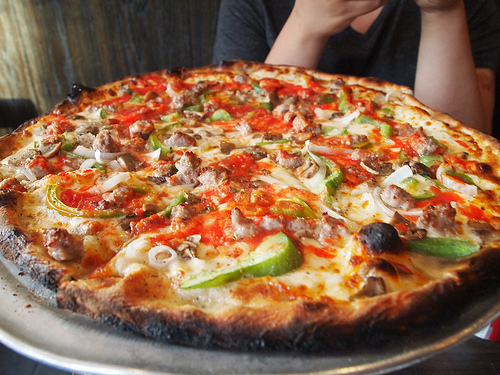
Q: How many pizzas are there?
A: One.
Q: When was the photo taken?
A: Daytime.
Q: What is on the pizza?
A: Toppings.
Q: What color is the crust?
A: Black.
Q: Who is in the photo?
A: One person.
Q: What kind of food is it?
A: Pizza.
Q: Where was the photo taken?
A: At a restaurant.